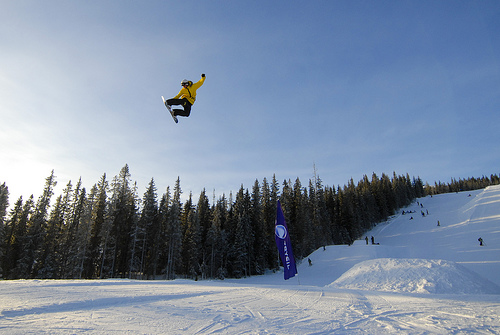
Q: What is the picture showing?
A: A man in the air.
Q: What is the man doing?
A: Snow boarding.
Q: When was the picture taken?
A: During the day.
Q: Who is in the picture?
A: A man.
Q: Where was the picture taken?
A: On a ski slope.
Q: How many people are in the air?
A: One.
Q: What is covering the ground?
A: Snow.